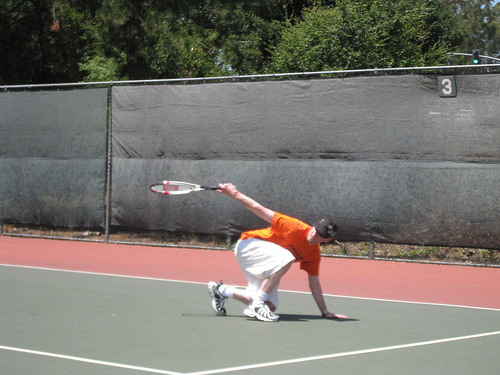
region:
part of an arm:
[311, 292, 322, 313]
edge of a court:
[398, 230, 400, 235]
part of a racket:
[227, 193, 234, 207]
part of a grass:
[398, 237, 404, 264]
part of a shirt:
[326, 294, 331, 314]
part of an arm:
[335, 327, 343, 350]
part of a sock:
[253, 291, 257, 303]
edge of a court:
[378, 285, 393, 343]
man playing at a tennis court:
[143, 153, 359, 338]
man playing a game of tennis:
[146, 167, 361, 334]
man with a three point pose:
[146, 162, 368, 332]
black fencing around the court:
[3, 68, 498, 264]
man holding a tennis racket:
[153, 175, 358, 332]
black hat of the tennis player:
[314, 215, 336, 239]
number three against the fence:
[431, 67, 455, 98]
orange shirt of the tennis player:
[241, 207, 333, 275]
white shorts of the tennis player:
[232, 237, 295, 310]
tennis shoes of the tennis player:
[208, 280, 285, 327]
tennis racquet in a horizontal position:
[146, 170, 234, 215]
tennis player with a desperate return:
[118, 151, 378, 334]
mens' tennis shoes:
[238, 289, 285, 336]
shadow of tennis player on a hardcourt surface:
[158, 296, 392, 337]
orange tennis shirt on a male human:
[223, 206, 351, 293]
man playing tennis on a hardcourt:
[116, 144, 381, 354]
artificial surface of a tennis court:
[10, 244, 477, 365]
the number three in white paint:
[433, 69, 461, 105]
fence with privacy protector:
[17, 61, 494, 276]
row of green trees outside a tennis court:
[0, 7, 487, 77]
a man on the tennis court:
[149, 149, 449, 367]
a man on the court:
[154, 126, 494, 374]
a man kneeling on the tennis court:
[149, 121, 427, 368]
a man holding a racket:
[148, 136, 335, 342]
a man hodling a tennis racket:
[133, 156, 325, 321]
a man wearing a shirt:
[159, 133, 443, 367]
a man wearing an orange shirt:
[200, 143, 347, 327]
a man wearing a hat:
[187, 190, 349, 355]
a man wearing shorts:
[221, 181, 342, 313]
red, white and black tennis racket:
[145, 177, 229, 199]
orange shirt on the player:
[233, 210, 325, 280]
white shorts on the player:
[233, 233, 296, 309]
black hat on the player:
[311, 210, 338, 239]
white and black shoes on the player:
[205, 278, 283, 323]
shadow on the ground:
[181, 307, 361, 326]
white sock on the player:
[250, 286, 270, 306]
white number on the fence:
[437, 76, 454, 98]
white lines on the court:
[1, 324, 499, 374]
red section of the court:
[0, 232, 499, 312]